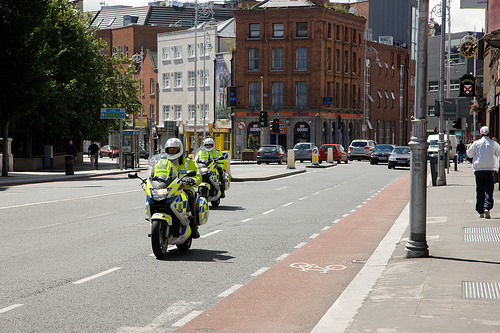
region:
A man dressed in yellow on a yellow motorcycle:
[126, 134, 209, 261]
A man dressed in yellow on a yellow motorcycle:
[188, 135, 234, 209]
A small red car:
[317, 143, 350, 167]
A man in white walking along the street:
[465, 123, 498, 220]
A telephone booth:
[117, 127, 141, 172]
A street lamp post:
[403, 0, 430, 262]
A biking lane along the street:
[175, 168, 411, 332]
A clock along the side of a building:
[458, 38, 478, 60]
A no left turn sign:
[234, 118, 249, 167]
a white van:
[426, 131, 457, 162]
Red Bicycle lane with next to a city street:
[185, 167, 411, 330]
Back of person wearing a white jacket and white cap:
[463, 124, 498, 219]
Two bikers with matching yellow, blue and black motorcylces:
[125, 113, 235, 258]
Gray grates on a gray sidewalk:
[457, 217, 496, 309]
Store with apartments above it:
[230, 6, 364, 158]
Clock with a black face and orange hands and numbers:
[458, 37, 480, 60]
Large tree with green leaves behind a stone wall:
[2, 0, 139, 179]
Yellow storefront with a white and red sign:
[181, 123, 231, 155]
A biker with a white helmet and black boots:
[135, 136, 215, 260]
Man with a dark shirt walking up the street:
[0, 132, 147, 186]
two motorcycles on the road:
[0, 120, 260, 315]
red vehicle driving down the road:
[311, 127, 356, 177]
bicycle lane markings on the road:
[269, 145, 415, 332]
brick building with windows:
[227, 4, 378, 93]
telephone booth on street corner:
[107, 115, 156, 182]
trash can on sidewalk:
[35, 136, 107, 186]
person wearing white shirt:
[456, 115, 498, 215]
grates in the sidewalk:
[433, 193, 498, 331]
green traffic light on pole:
[249, 70, 277, 137]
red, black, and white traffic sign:
[232, 111, 252, 136]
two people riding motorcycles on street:
[146, 133, 233, 259]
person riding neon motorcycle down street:
[137, 126, 209, 255]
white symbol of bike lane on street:
[288, 256, 348, 277]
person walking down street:
[465, 120, 497, 220]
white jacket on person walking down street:
[467, 130, 499, 170]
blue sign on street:
[98, 105, 125, 120]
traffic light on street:
[256, 105, 268, 129]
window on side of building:
[292, 46, 309, 74]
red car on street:
[320, 140, 344, 161]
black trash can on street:
[62, 153, 74, 178]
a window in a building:
[294, 47, 309, 72]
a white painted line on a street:
[273, 195, 294, 210]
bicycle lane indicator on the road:
[292, 255, 344, 277]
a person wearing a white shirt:
[466, 139, 498, 171]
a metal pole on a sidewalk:
[412, 9, 432, 259]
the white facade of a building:
[163, 35, 195, 46]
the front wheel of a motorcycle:
[150, 219, 170, 254]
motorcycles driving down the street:
[130, 113, 265, 267]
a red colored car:
[317, 143, 344, 165]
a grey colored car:
[255, 145, 285, 163]